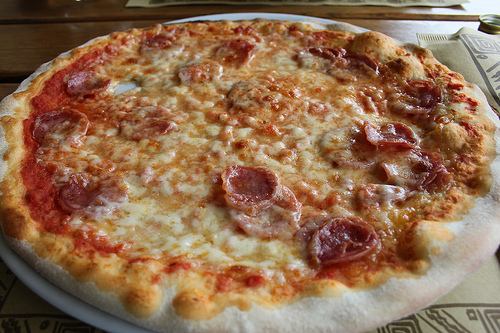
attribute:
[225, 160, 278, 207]
pepperoni — small, pink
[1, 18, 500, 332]
pizza — cooked, fully baked, large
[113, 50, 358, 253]
melted cheese — yummy, mozzarella, white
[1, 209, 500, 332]
crust — white, brown, browned, puffy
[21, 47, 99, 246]
sauce — concentrated, red, tomato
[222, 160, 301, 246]
pepperoni — stacked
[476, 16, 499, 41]
bottle cap — gold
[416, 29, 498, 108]
napkin — lined, designed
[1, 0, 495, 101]
table — brown, wood, slatted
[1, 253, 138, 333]
plate — white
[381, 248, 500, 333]
box — brass colored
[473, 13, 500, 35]
cap — gold